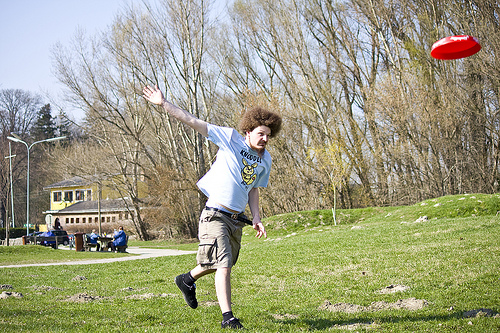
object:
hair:
[236, 107, 280, 159]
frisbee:
[430, 35, 482, 61]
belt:
[204, 206, 252, 226]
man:
[137, 86, 283, 331]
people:
[84, 224, 126, 253]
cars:
[26, 227, 70, 248]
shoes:
[173, 265, 245, 330]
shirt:
[192, 125, 271, 210]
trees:
[0, 10, 500, 238]